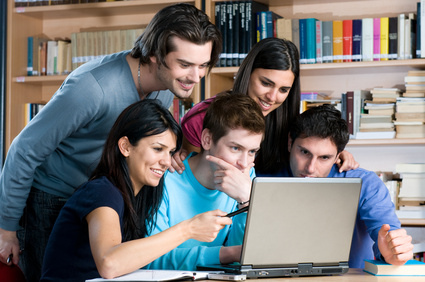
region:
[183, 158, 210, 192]
edge of a coolar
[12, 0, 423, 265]
the books on the shelves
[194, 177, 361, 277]
the laptop on the table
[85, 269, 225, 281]
the opened book on the table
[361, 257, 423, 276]
the book on the table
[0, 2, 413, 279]
the group of people at the table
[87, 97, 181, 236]
the dark hair on the woman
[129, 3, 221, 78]
the hair on the man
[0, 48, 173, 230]
the long shirt on the man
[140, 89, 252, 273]
the man in front of the laptop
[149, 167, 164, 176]
the smile on the woman's face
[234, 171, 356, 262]
this is a laptop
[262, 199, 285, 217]
the laptop is white in color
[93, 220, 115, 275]
the lady is light skinned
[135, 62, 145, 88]
this is a necklace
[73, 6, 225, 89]
this is a man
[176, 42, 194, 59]
the man is light skinned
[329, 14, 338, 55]
this is a book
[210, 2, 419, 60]
books on a bookshelf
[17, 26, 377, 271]
people staring at a computer screen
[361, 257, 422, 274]
a blue book on the table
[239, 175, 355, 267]
a laptop on a table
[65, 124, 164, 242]
a lady in a dark blue shirt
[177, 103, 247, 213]
a man in a light blue shirt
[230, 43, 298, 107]
a lady in a pink shirt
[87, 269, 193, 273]
an open book on the table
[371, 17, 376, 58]
a pink book on the shelf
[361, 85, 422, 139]
a stack of books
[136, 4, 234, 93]
head of a person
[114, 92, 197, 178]
head of a person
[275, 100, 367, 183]
head of a person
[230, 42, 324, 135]
head of a person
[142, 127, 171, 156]
eye of a person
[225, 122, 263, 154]
eye of a person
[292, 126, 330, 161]
eye of a person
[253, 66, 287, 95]
eye of a person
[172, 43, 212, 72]
eye of a person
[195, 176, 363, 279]
LAPTOP IS ON THE TABLE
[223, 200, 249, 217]
PEN IS POINTING AT LAP TOP SCREEN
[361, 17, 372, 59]
BOOK IS ON BOOK SHELF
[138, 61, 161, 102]
NECKLACE IS AROUND MANS NECK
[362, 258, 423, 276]
BOOK IS ON THE DESK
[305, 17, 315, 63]
book is on the bookcase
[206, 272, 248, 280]
cellphone is beside laptop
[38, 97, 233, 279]
lady is sitting in front of laptop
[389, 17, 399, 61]
BOOK IS ON BOOKCASE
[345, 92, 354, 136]
BOOK IS ON BOOKCASE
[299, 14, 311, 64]
a book on a book shelf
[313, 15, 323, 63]
a book on a book shelf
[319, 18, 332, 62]
a book on a book shelf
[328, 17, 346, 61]
a book on a book shelf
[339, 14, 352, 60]
a book on a book shelf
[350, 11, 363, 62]
a book on a book shelf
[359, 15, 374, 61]
a book on a book shelf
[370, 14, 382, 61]
a book on a book shelf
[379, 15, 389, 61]
a book on a book shelf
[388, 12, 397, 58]
a book on a book shelf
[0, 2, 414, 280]
group of people viewing computer screen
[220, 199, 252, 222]
writing instrument in woman's right hand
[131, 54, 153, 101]
chain necklace around man's neck